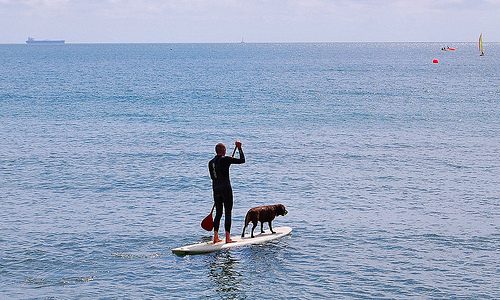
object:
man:
[199, 141, 246, 244]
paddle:
[201, 140, 241, 231]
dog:
[241, 202, 288, 238]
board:
[170, 224, 294, 254]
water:
[0, 43, 500, 299]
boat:
[478, 32, 489, 58]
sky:
[0, 2, 500, 47]